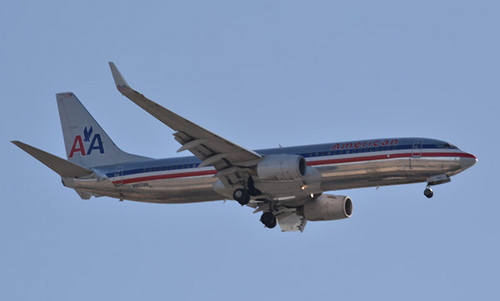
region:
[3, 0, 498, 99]
The sky is clear blue.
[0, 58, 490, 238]
The plane is silver.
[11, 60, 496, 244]
The plane has red and blue stripes.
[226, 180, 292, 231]
The wheels are out.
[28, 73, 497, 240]
The plane is flying.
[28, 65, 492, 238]
The plane is in the air.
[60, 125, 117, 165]
The AA is on the tail.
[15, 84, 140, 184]
The tail is white.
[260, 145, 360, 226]
The jets are silver.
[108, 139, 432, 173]
Many windows are on the side of the plane.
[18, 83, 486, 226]
silver plane flying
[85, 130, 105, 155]
blue letter A on gray background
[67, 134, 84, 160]
red letter A on gray background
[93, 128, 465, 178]
blue top half of airplane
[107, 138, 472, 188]
red and white stripes on the plane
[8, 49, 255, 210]
wings of the airplane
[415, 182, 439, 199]
front wheels of the airplane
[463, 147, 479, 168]
nose of the airplane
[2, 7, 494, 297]
blue sky plane is flying through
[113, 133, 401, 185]
row of windows on side of plane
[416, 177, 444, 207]
Front wheel of jet plane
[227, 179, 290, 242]
Rear wheels of jet plane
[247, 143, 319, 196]
Right engine of jet plane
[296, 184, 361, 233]
Left engine of jet plane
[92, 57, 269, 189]
Right wing of jet plane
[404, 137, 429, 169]
Right door of jet plane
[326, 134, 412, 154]
American painted on jet plane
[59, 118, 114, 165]
AA painted on tail of plane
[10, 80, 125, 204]
Tail section of jet plane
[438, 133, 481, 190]
Cockpit section of jet plane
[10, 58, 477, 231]
commercial airplane during flight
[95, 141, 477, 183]
blue, white and red stripes across body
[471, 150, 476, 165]
white light on tip of nose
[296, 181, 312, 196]
two white lights between engines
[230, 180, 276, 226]
curve of black wheels under plane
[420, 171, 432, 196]
black wheel hanging under plane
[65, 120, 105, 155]
blue wings between two letters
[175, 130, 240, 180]
pointy cylinders under wing flaps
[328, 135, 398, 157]
red lettering of company name over stripes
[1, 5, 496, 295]
clear light blue sky behind airplane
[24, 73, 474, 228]
A large plane in the air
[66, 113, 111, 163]
AA with logo on tail of plane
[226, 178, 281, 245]
Planes landing gear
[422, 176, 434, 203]
Front wheel under cockpit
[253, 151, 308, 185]
White engine on left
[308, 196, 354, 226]
White engine on right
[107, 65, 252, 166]
Left wing of plane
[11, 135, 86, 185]
Wing on back left near tail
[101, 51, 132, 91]
Tip of wing pointed up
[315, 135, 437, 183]
Red, white, blue and silver plane